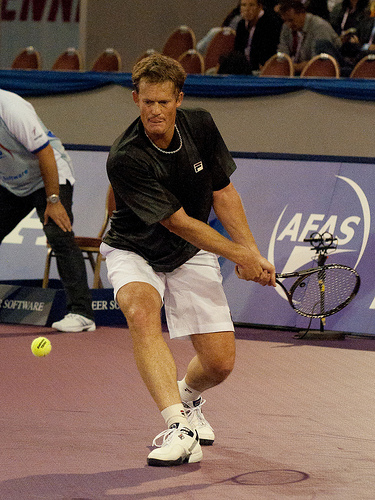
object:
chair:
[10, 44, 42, 68]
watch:
[47, 193, 60, 203]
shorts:
[99, 236, 235, 340]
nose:
[151, 101, 161, 115]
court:
[0, 322, 373, 498]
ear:
[176, 91, 184, 107]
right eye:
[144, 99, 154, 104]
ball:
[30, 337, 51, 359]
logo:
[194, 161, 204, 173]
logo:
[268, 169, 369, 311]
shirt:
[0, 85, 77, 196]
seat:
[260, 53, 294, 77]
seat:
[301, 52, 340, 76]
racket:
[274, 263, 360, 319]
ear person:
[98, 53, 273, 469]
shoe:
[52, 312, 97, 333]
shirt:
[101, 107, 237, 272]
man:
[0, 87, 96, 333]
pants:
[0, 179, 96, 322]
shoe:
[146, 427, 203, 466]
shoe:
[176, 380, 215, 445]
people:
[219, 0, 339, 72]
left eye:
[159, 100, 169, 104]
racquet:
[270, 259, 365, 324]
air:
[7, 273, 27, 342]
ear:
[132, 90, 137, 103]